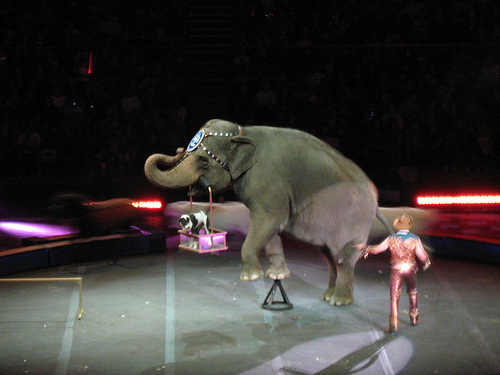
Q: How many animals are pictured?
A: Two.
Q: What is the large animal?
A: An elephant.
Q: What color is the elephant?
A: Grey.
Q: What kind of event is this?
A: A circus.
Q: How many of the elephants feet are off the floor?
A: Two.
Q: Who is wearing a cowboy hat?
A: The man.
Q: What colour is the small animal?
A: Black and white.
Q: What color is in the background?
A: Black.